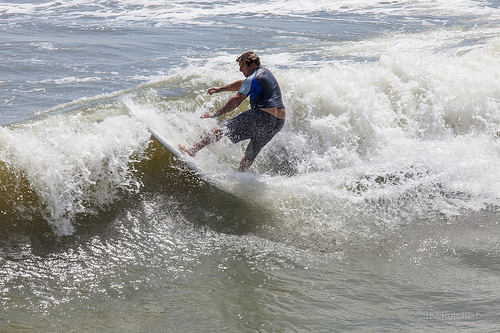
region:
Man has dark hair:
[228, 48, 270, 65]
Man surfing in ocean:
[25, 44, 417, 295]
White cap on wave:
[18, 117, 351, 191]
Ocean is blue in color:
[56, 12, 189, 72]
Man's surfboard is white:
[145, 139, 262, 227]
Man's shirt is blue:
[228, 72, 331, 134]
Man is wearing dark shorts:
[223, 105, 292, 192]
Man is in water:
[139, 36, 346, 241]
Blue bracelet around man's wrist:
[194, 98, 220, 153]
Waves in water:
[47, 40, 393, 233]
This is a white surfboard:
[64, 77, 274, 225]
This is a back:
[261, 103, 291, 122]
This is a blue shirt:
[229, 65, 291, 114]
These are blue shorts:
[216, 96, 294, 166]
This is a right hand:
[194, 81, 226, 93]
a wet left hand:
[200, 111, 219, 125]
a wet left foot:
[168, 143, 199, 158]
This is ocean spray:
[36, 146, 86, 181]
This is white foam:
[456, 194, 488, 199]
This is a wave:
[18, 55, 433, 214]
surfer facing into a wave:
[100, 37, 315, 208]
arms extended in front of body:
[186, 41, 296, 126]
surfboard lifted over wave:
[115, 45, 282, 245]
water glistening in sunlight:
[15, 181, 180, 286]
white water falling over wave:
[11, 70, 158, 247]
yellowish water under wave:
[1, 120, 183, 250]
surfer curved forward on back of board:
[175, 41, 295, 201]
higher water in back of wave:
[55, 35, 470, 240]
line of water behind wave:
[16, 60, 206, 125]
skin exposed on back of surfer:
[235, 95, 306, 128]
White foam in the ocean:
[357, 40, 498, 145]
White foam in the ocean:
[368, 127, 498, 230]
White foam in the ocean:
[288, 61, 415, 169]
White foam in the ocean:
[11, 107, 162, 240]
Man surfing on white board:
[105, 40, 324, 226]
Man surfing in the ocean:
[146, 42, 306, 229]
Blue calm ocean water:
[7, 6, 192, 99]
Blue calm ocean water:
[154, 7, 411, 46]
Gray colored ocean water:
[321, 223, 496, 323]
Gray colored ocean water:
[47, 245, 297, 325]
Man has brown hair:
[225, 45, 272, 81]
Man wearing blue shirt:
[223, 72, 310, 113]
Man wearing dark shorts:
[206, 102, 292, 166]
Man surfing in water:
[145, 107, 330, 251]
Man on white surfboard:
[147, 45, 301, 231]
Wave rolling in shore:
[50, 22, 383, 232]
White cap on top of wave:
[39, 48, 366, 278]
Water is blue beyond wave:
[41, 33, 111, 73]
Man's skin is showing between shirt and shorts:
[243, 99, 326, 141]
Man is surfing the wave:
[150, 39, 335, 280]